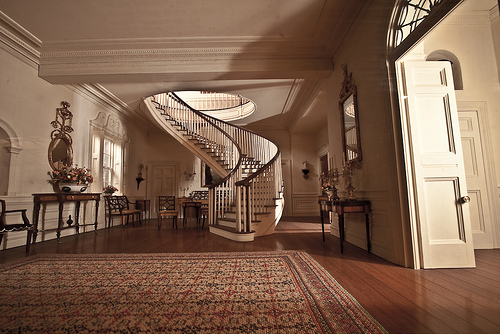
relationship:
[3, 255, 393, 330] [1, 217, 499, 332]
rug on floor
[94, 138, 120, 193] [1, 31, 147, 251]
window on wall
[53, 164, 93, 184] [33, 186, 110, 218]
potted flowers on a table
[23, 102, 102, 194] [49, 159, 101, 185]
mirror above flowers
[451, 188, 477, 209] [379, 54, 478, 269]
door knob on a painted door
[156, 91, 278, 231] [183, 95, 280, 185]
staircase behind bannister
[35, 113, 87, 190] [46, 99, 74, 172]
mirror with frame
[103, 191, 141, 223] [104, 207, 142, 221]
chairs with upholstery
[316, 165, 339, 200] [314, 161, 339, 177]
candleabra with candles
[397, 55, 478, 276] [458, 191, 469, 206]
door with handle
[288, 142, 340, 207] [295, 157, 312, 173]
sconce with candle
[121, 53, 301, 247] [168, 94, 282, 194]
staircase with trim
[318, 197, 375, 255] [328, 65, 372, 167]
table under mirror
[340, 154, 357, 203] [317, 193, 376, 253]
candelabra on table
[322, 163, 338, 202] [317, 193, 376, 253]
candelabra on table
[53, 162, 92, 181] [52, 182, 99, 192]
flowers in bowl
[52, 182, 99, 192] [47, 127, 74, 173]
bowl under mirror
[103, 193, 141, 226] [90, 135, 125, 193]
bench under window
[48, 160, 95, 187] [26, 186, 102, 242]
flower on table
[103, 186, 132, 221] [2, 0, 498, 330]
bench in hall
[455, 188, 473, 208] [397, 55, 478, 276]
knob on door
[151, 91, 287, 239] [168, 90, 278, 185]
white staircase with dark railing